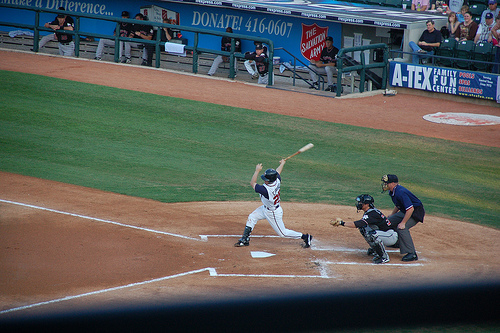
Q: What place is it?
A: It is a field.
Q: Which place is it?
A: It is a field.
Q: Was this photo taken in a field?
A: Yes, it was taken in a field.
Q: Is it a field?
A: Yes, it is a field.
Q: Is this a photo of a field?
A: Yes, it is showing a field.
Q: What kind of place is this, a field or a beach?
A: It is a field.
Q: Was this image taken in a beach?
A: No, the picture was taken in a field.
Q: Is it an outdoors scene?
A: Yes, it is outdoors.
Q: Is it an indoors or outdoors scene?
A: It is outdoors.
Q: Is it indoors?
A: No, it is outdoors.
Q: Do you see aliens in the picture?
A: No, there are no aliens.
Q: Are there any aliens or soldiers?
A: No, there are no aliens or soldiers.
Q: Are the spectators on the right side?
A: Yes, the spectators are on the right of the image.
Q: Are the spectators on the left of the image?
A: No, the spectators are on the right of the image.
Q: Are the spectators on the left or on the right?
A: The spectators are on the right of the image.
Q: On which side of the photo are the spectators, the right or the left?
A: The spectators are on the right of the image.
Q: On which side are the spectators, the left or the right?
A: The spectators are on the right of the image.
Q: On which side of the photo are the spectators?
A: The spectators are on the right of the image.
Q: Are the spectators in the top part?
A: Yes, the spectators are in the top of the image.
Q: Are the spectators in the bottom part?
A: No, the spectators are in the top of the image.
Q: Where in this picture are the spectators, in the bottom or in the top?
A: The spectators are in the top of the image.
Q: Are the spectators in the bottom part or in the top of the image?
A: The spectators are in the top of the image.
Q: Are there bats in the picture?
A: Yes, there is a bat.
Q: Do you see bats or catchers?
A: Yes, there is a bat.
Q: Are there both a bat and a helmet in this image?
A: Yes, there are both a bat and a helmet.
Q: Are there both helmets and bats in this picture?
A: Yes, there are both a bat and a helmet.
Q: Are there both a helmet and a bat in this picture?
A: Yes, there are both a bat and a helmet.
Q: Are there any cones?
A: No, there are no cones.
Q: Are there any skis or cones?
A: No, there are no cones or skis.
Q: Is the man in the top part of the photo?
A: Yes, the man is in the top of the image.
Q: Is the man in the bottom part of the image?
A: No, the man is in the top of the image.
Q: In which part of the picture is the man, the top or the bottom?
A: The man is in the top of the image.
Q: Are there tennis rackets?
A: No, there are no tennis rackets.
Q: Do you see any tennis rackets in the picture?
A: No, there are no tennis rackets.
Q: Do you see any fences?
A: Yes, there is a fence.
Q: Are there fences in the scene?
A: Yes, there is a fence.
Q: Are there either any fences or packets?
A: Yes, there is a fence.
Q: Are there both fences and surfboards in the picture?
A: No, there is a fence but no surfboards.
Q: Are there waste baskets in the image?
A: No, there are no waste baskets.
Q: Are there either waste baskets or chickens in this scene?
A: No, there are no waste baskets or chickens.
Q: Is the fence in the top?
A: Yes, the fence is in the top of the image.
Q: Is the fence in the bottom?
A: No, the fence is in the top of the image.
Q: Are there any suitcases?
A: No, there are no suitcases.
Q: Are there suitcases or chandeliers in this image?
A: No, there are no suitcases or chandeliers.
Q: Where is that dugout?
A: The dugout is on the field.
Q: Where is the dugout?
A: The dugout is on the field.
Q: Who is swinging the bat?
A: The player is swinging the bat.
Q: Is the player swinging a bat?
A: Yes, the player is swinging a bat.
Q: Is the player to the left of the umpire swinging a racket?
A: No, the player is swinging a bat.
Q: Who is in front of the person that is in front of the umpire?
A: The player is in front of the catcher.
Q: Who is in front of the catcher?
A: The player is in front of the catcher.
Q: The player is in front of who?
A: The player is in front of the catcher.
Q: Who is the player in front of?
A: The player is in front of the catcher.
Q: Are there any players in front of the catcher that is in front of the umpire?
A: Yes, there is a player in front of the catcher.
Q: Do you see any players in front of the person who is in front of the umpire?
A: Yes, there is a player in front of the catcher.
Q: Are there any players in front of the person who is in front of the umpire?
A: Yes, there is a player in front of the catcher.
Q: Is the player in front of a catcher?
A: Yes, the player is in front of a catcher.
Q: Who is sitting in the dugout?
A: The player is sitting in the dugout.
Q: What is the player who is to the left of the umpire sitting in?
A: The player is sitting in the dugout.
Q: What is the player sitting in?
A: The player is sitting in the dugout.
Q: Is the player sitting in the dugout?
A: Yes, the player is sitting in the dugout.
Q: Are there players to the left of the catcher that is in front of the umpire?
A: Yes, there is a player to the left of the catcher.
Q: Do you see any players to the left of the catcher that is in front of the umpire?
A: Yes, there is a player to the left of the catcher.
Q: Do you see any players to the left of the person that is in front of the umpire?
A: Yes, there is a player to the left of the catcher.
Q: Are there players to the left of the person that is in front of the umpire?
A: Yes, there is a player to the left of the catcher.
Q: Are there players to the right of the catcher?
A: No, the player is to the left of the catcher.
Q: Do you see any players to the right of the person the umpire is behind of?
A: No, the player is to the left of the catcher.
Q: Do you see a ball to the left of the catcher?
A: No, there is a player to the left of the catcher.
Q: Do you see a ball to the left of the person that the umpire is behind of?
A: No, there is a player to the left of the catcher.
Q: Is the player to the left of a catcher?
A: Yes, the player is to the left of a catcher.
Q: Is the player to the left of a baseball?
A: No, the player is to the left of a catcher.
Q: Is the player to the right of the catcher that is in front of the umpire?
A: No, the player is to the left of the catcher.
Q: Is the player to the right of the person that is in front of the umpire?
A: No, the player is to the left of the catcher.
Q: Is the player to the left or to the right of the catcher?
A: The player is to the left of the catcher.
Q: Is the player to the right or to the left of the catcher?
A: The player is to the left of the catcher.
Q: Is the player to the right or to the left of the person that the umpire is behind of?
A: The player is to the left of the catcher.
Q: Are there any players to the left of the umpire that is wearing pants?
A: Yes, there is a player to the left of the umpire.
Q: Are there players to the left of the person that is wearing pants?
A: Yes, there is a player to the left of the umpire.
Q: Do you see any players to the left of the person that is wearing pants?
A: Yes, there is a player to the left of the umpire.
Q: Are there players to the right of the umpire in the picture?
A: No, the player is to the left of the umpire.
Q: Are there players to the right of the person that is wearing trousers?
A: No, the player is to the left of the umpire.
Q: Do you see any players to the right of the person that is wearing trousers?
A: No, the player is to the left of the umpire.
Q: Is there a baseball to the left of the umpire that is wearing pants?
A: No, there is a player to the left of the umpire.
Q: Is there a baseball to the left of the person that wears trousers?
A: No, there is a player to the left of the umpire.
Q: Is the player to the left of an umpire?
A: Yes, the player is to the left of an umpire.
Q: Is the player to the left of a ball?
A: No, the player is to the left of an umpire.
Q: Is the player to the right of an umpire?
A: No, the player is to the left of an umpire.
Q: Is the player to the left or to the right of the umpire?
A: The player is to the left of the umpire.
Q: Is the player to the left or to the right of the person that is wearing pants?
A: The player is to the left of the umpire.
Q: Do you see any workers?
A: No, there are no workers.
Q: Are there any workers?
A: No, there are no workers.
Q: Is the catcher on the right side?
A: Yes, the catcher is on the right of the image.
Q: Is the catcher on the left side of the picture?
A: No, the catcher is on the right of the image.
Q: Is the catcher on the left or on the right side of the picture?
A: The catcher is on the right of the image.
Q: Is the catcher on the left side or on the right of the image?
A: The catcher is on the right of the image.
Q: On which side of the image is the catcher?
A: The catcher is on the right of the image.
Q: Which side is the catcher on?
A: The catcher is on the right of the image.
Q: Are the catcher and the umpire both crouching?
A: Yes, both the catcher and the umpire are crouching.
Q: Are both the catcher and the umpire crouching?
A: Yes, both the catcher and the umpire are crouching.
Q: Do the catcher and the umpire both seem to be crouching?
A: Yes, both the catcher and the umpire are crouching.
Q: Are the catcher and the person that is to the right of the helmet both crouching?
A: Yes, both the catcher and the umpire are crouching.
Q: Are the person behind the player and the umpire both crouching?
A: Yes, both the catcher and the umpire are crouching.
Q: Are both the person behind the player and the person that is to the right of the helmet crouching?
A: Yes, both the catcher and the umpire are crouching.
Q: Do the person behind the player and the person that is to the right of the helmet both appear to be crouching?
A: Yes, both the catcher and the umpire are crouching.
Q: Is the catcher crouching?
A: Yes, the catcher is crouching.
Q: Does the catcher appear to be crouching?
A: Yes, the catcher is crouching.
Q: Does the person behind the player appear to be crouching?
A: Yes, the catcher is crouching.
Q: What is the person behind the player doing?
A: The catcher is crouching.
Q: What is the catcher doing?
A: The catcher is crouching.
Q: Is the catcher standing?
A: No, the catcher is crouching.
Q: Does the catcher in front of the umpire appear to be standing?
A: No, the catcher is crouching.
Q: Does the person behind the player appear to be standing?
A: No, the catcher is crouching.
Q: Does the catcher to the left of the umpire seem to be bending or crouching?
A: The catcher is crouching.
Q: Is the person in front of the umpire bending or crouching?
A: The catcher is crouching.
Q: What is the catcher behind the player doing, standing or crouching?
A: The catcher is crouching.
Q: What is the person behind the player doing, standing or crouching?
A: The catcher is crouching.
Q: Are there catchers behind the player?
A: Yes, there is a catcher behind the player.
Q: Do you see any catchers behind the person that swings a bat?
A: Yes, there is a catcher behind the player.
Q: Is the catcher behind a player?
A: Yes, the catcher is behind a player.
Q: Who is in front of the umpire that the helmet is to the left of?
A: The catcher is in front of the umpire.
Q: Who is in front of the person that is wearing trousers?
A: The catcher is in front of the umpire.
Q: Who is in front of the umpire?
A: The catcher is in front of the umpire.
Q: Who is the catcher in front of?
A: The catcher is in front of the umpire.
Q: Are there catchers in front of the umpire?
A: Yes, there is a catcher in front of the umpire.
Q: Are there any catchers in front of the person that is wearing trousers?
A: Yes, there is a catcher in front of the umpire.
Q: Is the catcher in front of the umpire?
A: Yes, the catcher is in front of the umpire.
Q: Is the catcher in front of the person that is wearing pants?
A: Yes, the catcher is in front of the umpire.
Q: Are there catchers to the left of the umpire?
A: Yes, there is a catcher to the left of the umpire.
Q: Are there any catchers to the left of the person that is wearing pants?
A: Yes, there is a catcher to the left of the umpire.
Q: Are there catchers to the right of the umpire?
A: No, the catcher is to the left of the umpire.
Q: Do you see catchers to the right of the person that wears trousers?
A: No, the catcher is to the left of the umpire.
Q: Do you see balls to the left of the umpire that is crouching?
A: No, there is a catcher to the left of the umpire.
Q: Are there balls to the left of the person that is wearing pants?
A: No, there is a catcher to the left of the umpire.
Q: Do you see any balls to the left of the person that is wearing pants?
A: No, there is a catcher to the left of the umpire.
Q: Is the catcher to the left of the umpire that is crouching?
A: Yes, the catcher is to the left of the umpire.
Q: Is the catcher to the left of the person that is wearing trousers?
A: Yes, the catcher is to the left of the umpire.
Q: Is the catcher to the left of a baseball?
A: No, the catcher is to the left of the umpire.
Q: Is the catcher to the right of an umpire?
A: No, the catcher is to the left of an umpire.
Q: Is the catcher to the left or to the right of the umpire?
A: The catcher is to the left of the umpire.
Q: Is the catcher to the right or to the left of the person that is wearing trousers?
A: The catcher is to the left of the umpire.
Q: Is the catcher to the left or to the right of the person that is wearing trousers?
A: The catcher is to the left of the umpire.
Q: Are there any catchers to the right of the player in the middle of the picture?
A: Yes, there is a catcher to the right of the player.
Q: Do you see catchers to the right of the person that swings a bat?
A: Yes, there is a catcher to the right of the player.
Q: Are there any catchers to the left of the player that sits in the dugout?
A: No, the catcher is to the right of the player.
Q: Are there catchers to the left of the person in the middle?
A: No, the catcher is to the right of the player.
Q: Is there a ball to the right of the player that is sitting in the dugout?
A: No, there is a catcher to the right of the player.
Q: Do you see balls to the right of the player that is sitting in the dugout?
A: No, there is a catcher to the right of the player.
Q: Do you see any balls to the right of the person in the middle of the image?
A: No, there is a catcher to the right of the player.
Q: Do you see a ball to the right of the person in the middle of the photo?
A: No, there is a catcher to the right of the player.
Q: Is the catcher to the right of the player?
A: Yes, the catcher is to the right of the player.